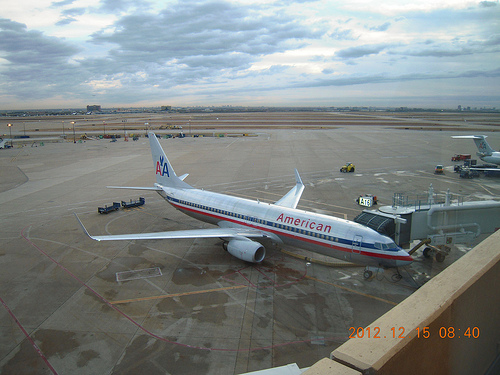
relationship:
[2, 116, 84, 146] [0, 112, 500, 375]
lights on edge of airport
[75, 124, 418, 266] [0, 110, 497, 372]
airplane on edge of tarmac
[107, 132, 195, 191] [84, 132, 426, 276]
tail of airplane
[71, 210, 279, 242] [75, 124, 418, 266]
wing of airplane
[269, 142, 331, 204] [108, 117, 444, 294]
wing of airplane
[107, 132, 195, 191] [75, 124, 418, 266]
tail of airplane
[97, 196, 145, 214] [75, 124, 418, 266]
luggage carrier behind airplane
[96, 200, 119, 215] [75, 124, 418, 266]
luggage carrier behind airplane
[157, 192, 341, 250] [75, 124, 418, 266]
windows of airplane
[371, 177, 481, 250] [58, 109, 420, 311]
building next to airplane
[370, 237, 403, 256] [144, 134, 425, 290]
window of airplane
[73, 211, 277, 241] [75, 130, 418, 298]
wing of plane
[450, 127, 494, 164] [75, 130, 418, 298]
tail of plane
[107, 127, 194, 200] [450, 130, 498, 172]
tail of plane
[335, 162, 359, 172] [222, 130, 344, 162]
vehicle on runway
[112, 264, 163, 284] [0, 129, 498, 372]
square on runway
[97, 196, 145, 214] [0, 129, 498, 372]
luggage carrier on runway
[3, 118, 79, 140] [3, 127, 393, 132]
lights on runway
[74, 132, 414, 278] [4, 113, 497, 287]
airplane at airport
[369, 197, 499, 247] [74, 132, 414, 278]
corridor into airplane